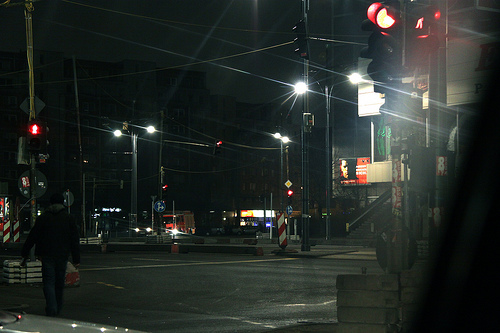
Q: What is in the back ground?
A: Lights.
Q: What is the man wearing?
A: Jacket.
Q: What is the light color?
A: Red.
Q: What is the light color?
A: White.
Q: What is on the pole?
A: Traffic light.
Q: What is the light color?
A: Red.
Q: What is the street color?
A: Gray.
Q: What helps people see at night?
A: Lights.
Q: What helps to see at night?
A: Lights.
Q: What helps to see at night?
A: Lights.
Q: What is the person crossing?
A: Street.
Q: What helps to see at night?
A: Lights.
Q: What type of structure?
A: Building.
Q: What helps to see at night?
A: Lights.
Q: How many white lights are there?
A: Six.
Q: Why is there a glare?
A: Photo anomaly.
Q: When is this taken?
A: Night time.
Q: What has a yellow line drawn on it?
A: The street.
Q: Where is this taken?
A: At night in the city streets.